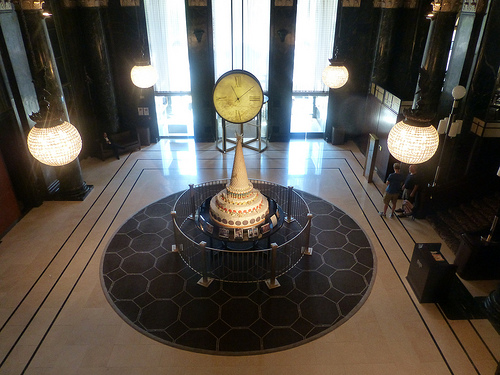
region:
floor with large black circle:
[52, 145, 417, 366]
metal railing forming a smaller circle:
[164, 166, 327, 303]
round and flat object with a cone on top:
[199, 125, 281, 262]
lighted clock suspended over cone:
[202, 2, 266, 127]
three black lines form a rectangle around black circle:
[10, 125, 485, 365]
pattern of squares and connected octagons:
[97, 200, 367, 355]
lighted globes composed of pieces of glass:
[22, 52, 444, 177]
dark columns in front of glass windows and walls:
[17, 0, 437, 210]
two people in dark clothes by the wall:
[370, 152, 430, 222]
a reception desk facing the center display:
[390, 213, 483, 335]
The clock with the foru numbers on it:
[208, 62, 267, 126]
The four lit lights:
[25, 61, 441, 181]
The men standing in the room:
[381, 159, 421, 221]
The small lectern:
[404, 237, 457, 309]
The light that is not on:
[449, 83, 467, 105]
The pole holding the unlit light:
[425, 98, 458, 201]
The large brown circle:
[96, 176, 377, 362]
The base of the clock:
[198, 131, 282, 240]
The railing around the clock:
[160, 176, 316, 293]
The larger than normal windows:
[140, 1, 347, 148]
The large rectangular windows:
[136, 0, 344, 141]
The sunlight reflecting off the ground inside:
[161, 135, 324, 197]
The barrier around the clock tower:
[155, 171, 322, 293]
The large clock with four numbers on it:
[207, 69, 264, 124]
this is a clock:
[215, 72, 266, 122]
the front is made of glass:
[222, 79, 257, 113]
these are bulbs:
[20, 52, 445, 171]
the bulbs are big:
[19, 52, 440, 179]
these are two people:
[383, 165, 418, 215]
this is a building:
[2, 2, 498, 362]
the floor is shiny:
[285, 136, 325, 180]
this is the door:
[151, 10, 205, 135]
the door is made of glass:
[156, 10, 183, 47]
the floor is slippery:
[358, 297, 425, 373]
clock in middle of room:
[202, 59, 274, 131]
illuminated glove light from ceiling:
[384, 104, 448, 175]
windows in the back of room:
[294, 4, 342, 64]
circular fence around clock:
[164, 237, 324, 285]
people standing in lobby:
[381, 158, 429, 223]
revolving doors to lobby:
[217, 121, 270, 160]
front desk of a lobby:
[397, 232, 471, 322]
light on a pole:
[424, 77, 473, 223]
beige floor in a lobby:
[25, 226, 53, 256]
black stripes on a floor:
[46, 243, 84, 313]